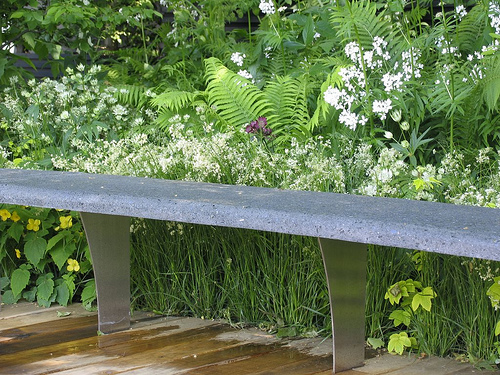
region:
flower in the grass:
[415, 284, 438, 316]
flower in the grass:
[377, 332, 413, 353]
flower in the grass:
[67, 255, 84, 270]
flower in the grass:
[57, 217, 76, 233]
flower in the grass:
[247, 162, 271, 184]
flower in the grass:
[24, 216, 43, 236]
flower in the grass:
[0, 212, 16, 228]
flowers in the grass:
[382, 324, 412, 349]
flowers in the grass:
[360, 183, 402, 210]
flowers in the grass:
[200, 155, 229, 173]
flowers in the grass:
[97, 143, 112, 153]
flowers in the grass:
[93, 142, 125, 168]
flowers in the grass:
[363, 165, 390, 185]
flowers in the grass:
[406, 172, 435, 189]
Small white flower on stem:
[362, 91, 414, 121]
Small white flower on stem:
[450, 3, 472, 19]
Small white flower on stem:
[481, 2, 498, 54]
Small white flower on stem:
[460, 51, 495, 94]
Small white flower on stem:
[399, 41, 433, 86]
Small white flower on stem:
[360, 33, 401, 73]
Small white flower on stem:
[368, 95, 396, 111]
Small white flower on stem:
[223, 41, 268, 66]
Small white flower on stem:
[232, 66, 268, 94]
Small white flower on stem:
[318, 38, 386, 130]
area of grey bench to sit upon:
[337, 189, 377, 249]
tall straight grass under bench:
[261, 256, 320, 320]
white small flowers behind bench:
[319, 46, 386, 136]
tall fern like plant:
[199, 56, 268, 138]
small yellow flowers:
[21, 211, 79, 258]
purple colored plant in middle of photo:
[248, 109, 308, 159]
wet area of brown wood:
[147, 321, 205, 371]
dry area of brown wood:
[393, 351, 422, 373]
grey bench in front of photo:
[0, 151, 350, 268]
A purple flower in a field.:
[241, 107, 278, 147]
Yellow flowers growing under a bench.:
[4, 200, 91, 314]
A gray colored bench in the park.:
[0, 166, 499, 373]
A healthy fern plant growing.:
[152, 46, 339, 139]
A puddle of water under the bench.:
[0, 310, 354, 374]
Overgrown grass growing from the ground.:
[143, 232, 328, 347]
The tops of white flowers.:
[320, 36, 425, 140]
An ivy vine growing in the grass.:
[387, 277, 439, 363]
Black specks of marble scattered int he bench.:
[191, 204, 398, 222]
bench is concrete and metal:
[1, 166, 499, 373]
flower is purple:
[244, 113, 275, 139]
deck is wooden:
[1, 295, 498, 374]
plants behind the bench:
[1, 1, 499, 362]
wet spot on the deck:
[1, 294, 499, 374]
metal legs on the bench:
[1, 167, 499, 368]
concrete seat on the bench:
[2, 166, 495, 371]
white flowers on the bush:
[226, 3, 498, 156]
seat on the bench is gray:
[1, 168, 499, 374]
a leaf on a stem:
[383, 335, 413, 354]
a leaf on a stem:
[391, 308, 411, 328]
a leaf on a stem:
[413, 284, 438, 315]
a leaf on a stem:
[58, 281, 70, 301]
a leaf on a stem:
[39, 277, 62, 309]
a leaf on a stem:
[6, 271, 29, 298]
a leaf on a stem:
[21, 232, 46, 271]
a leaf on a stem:
[47, 242, 77, 267]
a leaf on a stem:
[41, 232, 69, 250]